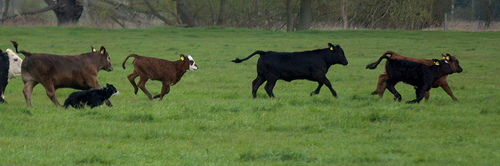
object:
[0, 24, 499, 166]
large pasture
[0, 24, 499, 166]
farm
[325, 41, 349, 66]
head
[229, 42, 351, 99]
cow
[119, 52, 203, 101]
cow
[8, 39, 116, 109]
cow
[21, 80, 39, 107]
leg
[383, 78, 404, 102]
leg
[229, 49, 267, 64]
tail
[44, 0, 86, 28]
trunks